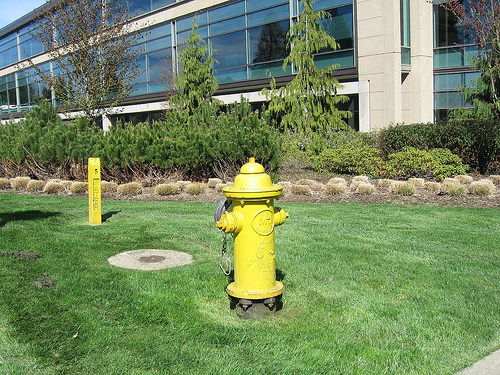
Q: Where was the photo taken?
A: It was taken at the lawn.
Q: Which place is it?
A: It is a lawn.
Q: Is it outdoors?
A: Yes, it is outdoors.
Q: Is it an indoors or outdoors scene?
A: It is outdoors.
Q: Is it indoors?
A: No, it is outdoors.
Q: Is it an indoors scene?
A: No, it is outdoors.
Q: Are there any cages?
A: No, there are no cages.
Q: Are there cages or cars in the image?
A: No, there are no cages or cars.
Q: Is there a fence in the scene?
A: No, there are no fences.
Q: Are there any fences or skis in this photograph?
A: No, there are no fences or skis.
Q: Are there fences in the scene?
A: No, there are no fences.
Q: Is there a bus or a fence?
A: No, there are no fences or buses.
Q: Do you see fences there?
A: No, there are no fences.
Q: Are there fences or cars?
A: No, there are no fences or cars.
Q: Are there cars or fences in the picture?
A: No, there are no fences or cars.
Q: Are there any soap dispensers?
A: No, there are no soap dispensers.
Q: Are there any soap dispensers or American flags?
A: No, there are no soap dispensers or American flags.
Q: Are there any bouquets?
A: No, there are no bouquets.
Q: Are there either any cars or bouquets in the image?
A: No, there are no bouquets or cars.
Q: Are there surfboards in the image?
A: No, there are no surfboards.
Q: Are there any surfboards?
A: No, there are no surfboards.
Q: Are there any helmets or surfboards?
A: No, there are no surfboards or helmets.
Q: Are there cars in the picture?
A: No, there are no cars.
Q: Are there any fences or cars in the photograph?
A: No, there are no cars or fences.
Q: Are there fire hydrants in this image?
A: Yes, there is a fire hydrant.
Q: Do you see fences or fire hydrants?
A: Yes, there is a fire hydrant.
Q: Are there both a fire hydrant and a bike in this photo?
A: No, there is a fire hydrant but no bikes.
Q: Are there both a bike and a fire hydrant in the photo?
A: No, there is a fire hydrant but no bikes.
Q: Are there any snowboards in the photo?
A: No, there are no snowboards.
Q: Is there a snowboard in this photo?
A: No, there are no snowboards.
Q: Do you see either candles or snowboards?
A: No, there are no snowboards or candles.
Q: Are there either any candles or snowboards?
A: No, there are no snowboards or candles.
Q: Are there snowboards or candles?
A: No, there are no snowboards or candles.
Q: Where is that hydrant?
A: The hydrant is on the lawn.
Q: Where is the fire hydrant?
A: The hydrant is on the lawn.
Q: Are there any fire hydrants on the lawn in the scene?
A: Yes, there is a fire hydrant on the lawn.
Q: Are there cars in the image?
A: No, there are no cars.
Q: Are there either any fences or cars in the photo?
A: No, there are no cars or fences.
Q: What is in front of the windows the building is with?
A: The tree is in front of the windows.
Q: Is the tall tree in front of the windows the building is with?
A: Yes, the tree is in front of the windows.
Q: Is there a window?
A: Yes, there are windows.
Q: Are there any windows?
A: Yes, there are windows.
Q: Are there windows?
A: Yes, there are windows.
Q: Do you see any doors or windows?
A: Yes, there are windows.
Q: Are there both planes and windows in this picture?
A: No, there are windows but no airplanes.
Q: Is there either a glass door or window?
A: Yes, there are glass windows.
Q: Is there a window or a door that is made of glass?
A: Yes, the windows are made of glass.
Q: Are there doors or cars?
A: No, there are no cars or doors.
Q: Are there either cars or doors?
A: No, there are no cars or doors.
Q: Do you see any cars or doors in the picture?
A: No, there are no cars or doors.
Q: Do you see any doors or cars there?
A: No, there are no cars or doors.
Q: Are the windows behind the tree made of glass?
A: Yes, the windows are made of glass.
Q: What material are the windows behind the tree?
A: The windows are made of glass.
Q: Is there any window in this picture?
A: Yes, there are windows.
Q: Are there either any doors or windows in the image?
A: Yes, there are windows.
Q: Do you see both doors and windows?
A: No, there are windows but no doors.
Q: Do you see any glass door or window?
A: Yes, there are glass windows.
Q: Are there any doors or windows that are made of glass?
A: Yes, the windows are made of glass.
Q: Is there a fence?
A: No, there are no fences.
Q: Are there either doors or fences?
A: No, there are no fences or doors.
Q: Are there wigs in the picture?
A: No, there are no wigs.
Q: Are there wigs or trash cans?
A: No, there are no wigs or trash cans.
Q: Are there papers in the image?
A: No, there are no papers.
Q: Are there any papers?
A: No, there are no papers.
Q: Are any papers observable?
A: No, there are no papers.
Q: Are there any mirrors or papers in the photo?
A: No, there are no papers or mirrors.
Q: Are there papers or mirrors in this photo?
A: No, there are no papers or mirrors.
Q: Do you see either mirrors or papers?
A: No, there are no papers or mirrors.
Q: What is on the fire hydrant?
A: The chain is on the fire hydrant.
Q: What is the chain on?
A: The chain is on the fire hydrant.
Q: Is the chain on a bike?
A: No, the chain is on a fire hydrant.